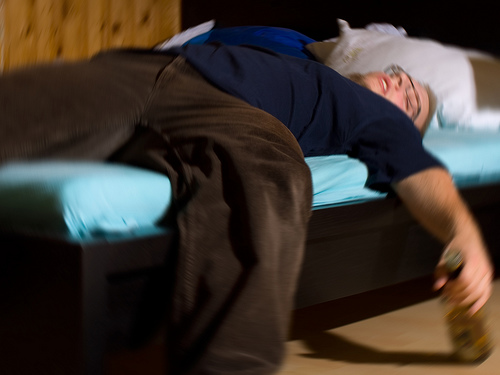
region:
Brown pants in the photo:
[182, 93, 315, 360]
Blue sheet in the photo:
[32, 163, 147, 215]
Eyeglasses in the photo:
[391, 51, 426, 117]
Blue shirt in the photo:
[265, 54, 362, 138]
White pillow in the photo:
[344, 29, 455, 69]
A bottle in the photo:
[437, 272, 491, 361]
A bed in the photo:
[2, 1, 497, 358]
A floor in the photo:
[319, 323, 441, 373]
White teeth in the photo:
[377, 72, 393, 101]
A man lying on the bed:
[7, 27, 494, 349]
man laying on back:
[16, 24, 481, 374]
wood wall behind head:
[11, 2, 178, 62]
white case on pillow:
[328, 29, 474, 125]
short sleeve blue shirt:
[188, 40, 442, 180]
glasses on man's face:
[387, 60, 418, 117]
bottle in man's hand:
[436, 245, 493, 357]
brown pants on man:
[0, 52, 308, 342]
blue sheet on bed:
[13, 125, 495, 234]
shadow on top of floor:
[307, 331, 457, 367]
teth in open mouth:
[376, 72, 391, 97]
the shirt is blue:
[200, 18, 326, 176]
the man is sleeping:
[298, 25, 460, 194]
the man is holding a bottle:
[393, 178, 491, 373]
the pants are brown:
[117, 130, 282, 325]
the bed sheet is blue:
[308, 134, 360, 216]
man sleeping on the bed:
[167, 17, 429, 172]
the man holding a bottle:
[356, 143, 476, 373]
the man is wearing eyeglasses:
[353, 45, 430, 146]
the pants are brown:
[118, 38, 325, 305]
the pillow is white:
[325, 10, 496, 135]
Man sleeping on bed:
[15, 20, 497, 362]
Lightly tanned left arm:
[380, 165, 492, 310]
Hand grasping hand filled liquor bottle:
[430, 235, 496, 370]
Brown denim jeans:
[25, 60, 320, 368]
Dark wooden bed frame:
[0, 195, 415, 356]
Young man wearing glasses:
[355, 63, 425, 125]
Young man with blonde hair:
[362, 60, 442, 137]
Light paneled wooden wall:
[10, 6, 176, 48]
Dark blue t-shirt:
[180, 38, 437, 188]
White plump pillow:
[338, 17, 495, 129]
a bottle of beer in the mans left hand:
[436, 243, 496, 363]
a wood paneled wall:
[0, 0, 178, 65]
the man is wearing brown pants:
[2, 51, 313, 372]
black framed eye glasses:
[385, 60, 422, 125]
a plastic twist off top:
[443, 245, 465, 273]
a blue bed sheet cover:
[1, 165, 171, 242]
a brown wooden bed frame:
[0, 233, 170, 373]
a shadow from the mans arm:
[295, 325, 455, 365]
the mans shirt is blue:
[297, 38, 440, 188]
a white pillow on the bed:
[336, 15, 476, 127]